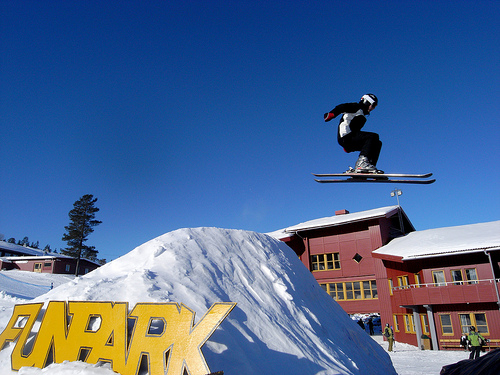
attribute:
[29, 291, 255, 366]
funpark — yellow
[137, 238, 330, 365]
snow — white, hill, mounded, piled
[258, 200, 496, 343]
building — red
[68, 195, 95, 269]
tree — large, pine, green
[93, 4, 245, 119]
sky — blue, clear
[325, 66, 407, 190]
skier — in air, skiing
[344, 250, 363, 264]
window — diamond-shaped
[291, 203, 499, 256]
roof — snow-covered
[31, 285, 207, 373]
sign — yellow, funpark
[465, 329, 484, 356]
jacket — green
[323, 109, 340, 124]
gloves — black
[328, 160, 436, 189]
skis — blue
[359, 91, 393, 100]
helmet — black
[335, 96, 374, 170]
clothes — black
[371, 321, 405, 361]
person — standing